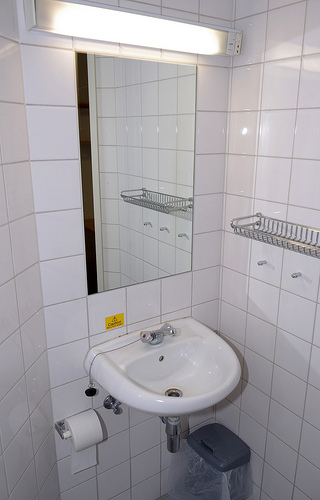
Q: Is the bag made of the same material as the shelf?
A: No, the bag is made of plastic and the shelf is made of metal.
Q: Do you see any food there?
A: No, there is no food.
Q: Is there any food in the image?
A: No, there is no food.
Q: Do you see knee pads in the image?
A: No, there are no knee pads.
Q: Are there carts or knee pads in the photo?
A: No, there are no knee pads or carts.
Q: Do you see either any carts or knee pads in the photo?
A: No, there are no knee pads or carts.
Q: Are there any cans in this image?
A: Yes, there is a can.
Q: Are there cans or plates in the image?
A: Yes, there is a can.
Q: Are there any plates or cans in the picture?
A: Yes, there is a can.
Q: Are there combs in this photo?
A: No, there are no combs.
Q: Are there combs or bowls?
A: No, there are no combs or bowls.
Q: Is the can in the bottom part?
A: Yes, the can is in the bottom of the image.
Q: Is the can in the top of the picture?
A: No, the can is in the bottom of the image.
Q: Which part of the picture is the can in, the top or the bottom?
A: The can is in the bottom of the image.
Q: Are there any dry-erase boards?
A: No, there are no dry-erase boards.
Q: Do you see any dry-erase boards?
A: No, there are no dry-erase boards.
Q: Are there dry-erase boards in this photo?
A: No, there are no dry-erase boards.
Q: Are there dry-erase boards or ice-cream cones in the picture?
A: No, there are no dry-erase boards or ice-cream cones.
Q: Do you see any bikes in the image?
A: No, there are no bikes.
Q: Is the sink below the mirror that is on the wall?
A: Yes, the sink is below the mirror.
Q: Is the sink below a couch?
A: No, the sink is below the mirror.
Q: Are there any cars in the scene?
A: No, there are no cars.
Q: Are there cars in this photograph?
A: No, there are no cars.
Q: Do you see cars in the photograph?
A: No, there are no cars.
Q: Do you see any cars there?
A: No, there are no cars.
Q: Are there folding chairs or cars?
A: No, there are no cars or folding chairs.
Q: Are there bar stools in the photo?
A: No, there are no bar stools.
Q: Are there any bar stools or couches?
A: No, there are no bar stools or couches.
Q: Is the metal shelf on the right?
A: Yes, the shelf is on the right of the image.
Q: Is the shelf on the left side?
A: No, the shelf is on the right of the image.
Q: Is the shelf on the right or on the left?
A: The shelf is on the right of the image.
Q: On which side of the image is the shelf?
A: The shelf is on the right of the image.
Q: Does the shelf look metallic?
A: Yes, the shelf is metallic.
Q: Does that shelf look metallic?
A: Yes, the shelf is metallic.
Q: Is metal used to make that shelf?
A: Yes, the shelf is made of metal.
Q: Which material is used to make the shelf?
A: The shelf is made of metal.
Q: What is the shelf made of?
A: The shelf is made of metal.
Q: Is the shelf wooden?
A: No, the shelf is metallic.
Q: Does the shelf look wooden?
A: No, the shelf is metallic.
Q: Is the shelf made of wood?
A: No, the shelf is made of metal.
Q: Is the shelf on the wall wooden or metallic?
A: The shelf is metallic.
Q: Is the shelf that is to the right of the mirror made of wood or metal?
A: The shelf is made of metal.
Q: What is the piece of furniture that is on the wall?
A: The piece of furniture is a shelf.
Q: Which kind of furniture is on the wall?
A: The piece of furniture is a shelf.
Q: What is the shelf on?
A: The shelf is on the wall.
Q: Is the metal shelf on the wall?
A: Yes, the shelf is on the wall.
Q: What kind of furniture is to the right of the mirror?
A: The piece of furniture is a shelf.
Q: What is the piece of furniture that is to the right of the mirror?
A: The piece of furniture is a shelf.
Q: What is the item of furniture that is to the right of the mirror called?
A: The piece of furniture is a shelf.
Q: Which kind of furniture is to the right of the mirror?
A: The piece of furniture is a shelf.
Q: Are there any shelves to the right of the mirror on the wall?
A: Yes, there is a shelf to the right of the mirror.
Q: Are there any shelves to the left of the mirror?
A: No, the shelf is to the right of the mirror.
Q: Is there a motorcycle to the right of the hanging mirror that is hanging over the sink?
A: No, there is a shelf to the right of the mirror.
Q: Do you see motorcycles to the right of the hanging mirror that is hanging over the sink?
A: No, there is a shelf to the right of the mirror.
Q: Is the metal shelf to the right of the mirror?
A: Yes, the shelf is to the right of the mirror.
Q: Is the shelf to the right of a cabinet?
A: No, the shelf is to the right of the mirror.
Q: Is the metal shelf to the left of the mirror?
A: No, the shelf is to the right of the mirror.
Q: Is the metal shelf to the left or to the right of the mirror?
A: The shelf is to the right of the mirror.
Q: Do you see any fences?
A: No, there are no fences.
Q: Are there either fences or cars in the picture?
A: No, there are no fences or cars.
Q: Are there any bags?
A: Yes, there is a bag.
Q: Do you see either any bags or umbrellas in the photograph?
A: Yes, there is a bag.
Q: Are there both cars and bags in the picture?
A: No, there is a bag but no cars.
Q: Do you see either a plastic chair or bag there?
A: Yes, there is a plastic bag.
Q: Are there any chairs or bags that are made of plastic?
A: Yes, the bag is made of plastic.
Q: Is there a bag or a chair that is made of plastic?
A: Yes, the bag is made of plastic.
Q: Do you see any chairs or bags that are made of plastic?
A: Yes, the bag is made of plastic.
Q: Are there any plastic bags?
A: Yes, there is a bag that is made of plastic.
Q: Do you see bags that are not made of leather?
A: Yes, there is a bag that is made of plastic.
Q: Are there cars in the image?
A: No, there are no cars.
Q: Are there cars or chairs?
A: No, there are no cars or chairs.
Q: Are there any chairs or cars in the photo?
A: No, there are no cars or chairs.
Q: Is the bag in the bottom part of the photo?
A: Yes, the bag is in the bottom of the image.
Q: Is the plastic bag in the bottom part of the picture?
A: Yes, the bag is in the bottom of the image.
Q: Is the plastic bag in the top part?
A: No, the bag is in the bottom of the image.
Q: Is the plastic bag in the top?
A: No, the bag is in the bottom of the image.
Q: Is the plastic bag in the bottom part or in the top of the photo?
A: The bag is in the bottom of the image.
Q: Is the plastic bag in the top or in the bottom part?
A: The bag is in the bottom of the image.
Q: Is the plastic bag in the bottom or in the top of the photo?
A: The bag is in the bottom of the image.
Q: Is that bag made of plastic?
A: Yes, the bag is made of plastic.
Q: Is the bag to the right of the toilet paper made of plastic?
A: Yes, the bag is made of plastic.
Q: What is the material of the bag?
A: The bag is made of plastic.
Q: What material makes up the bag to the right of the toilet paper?
A: The bag is made of plastic.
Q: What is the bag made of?
A: The bag is made of plastic.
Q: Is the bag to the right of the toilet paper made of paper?
A: No, the bag is made of plastic.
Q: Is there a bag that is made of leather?
A: No, there is a bag but it is made of plastic.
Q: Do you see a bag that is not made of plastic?
A: No, there is a bag but it is made of plastic.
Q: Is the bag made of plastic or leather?
A: The bag is made of plastic.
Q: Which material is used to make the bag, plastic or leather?
A: The bag is made of plastic.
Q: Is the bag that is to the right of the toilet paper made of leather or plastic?
A: The bag is made of plastic.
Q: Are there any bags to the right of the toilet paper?
A: Yes, there is a bag to the right of the toilet paper.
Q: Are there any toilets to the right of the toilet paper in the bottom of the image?
A: No, there is a bag to the right of the toilet paper.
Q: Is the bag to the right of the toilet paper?
A: Yes, the bag is to the right of the toilet paper.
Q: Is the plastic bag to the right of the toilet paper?
A: Yes, the bag is to the right of the toilet paper.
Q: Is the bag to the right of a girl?
A: No, the bag is to the right of the toilet paper.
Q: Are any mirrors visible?
A: Yes, there is a mirror.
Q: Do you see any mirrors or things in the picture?
A: Yes, there is a mirror.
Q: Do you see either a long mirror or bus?
A: Yes, there is a long mirror.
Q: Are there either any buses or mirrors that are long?
A: Yes, the mirror is long.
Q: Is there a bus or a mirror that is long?
A: Yes, the mirror is long.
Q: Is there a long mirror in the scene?
A: Yes, there is a long mirror.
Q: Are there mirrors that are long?
A: Yes, there is a mirror that is long.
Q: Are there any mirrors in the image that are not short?
A: Yes, there is a long mirror.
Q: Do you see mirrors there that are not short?
A: Yes, there is a long mirror.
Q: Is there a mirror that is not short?
A: Yes, there is a long mirror.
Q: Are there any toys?
A: No, there are no toys.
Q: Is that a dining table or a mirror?
A: That is a mirror.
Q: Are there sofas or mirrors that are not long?
A: No, there is a mirror but it is long.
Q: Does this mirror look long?
A: Yes, the mirror is long.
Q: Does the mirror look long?
A: Yes, the mirror is long.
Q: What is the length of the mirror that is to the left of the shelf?
A: The mirror is long.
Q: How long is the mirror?
A: The mirror is long.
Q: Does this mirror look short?
A: No, the mirror is long.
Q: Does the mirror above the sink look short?
A: No, the mirror is long.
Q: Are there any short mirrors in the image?
A: No, there is a mirror but it is long.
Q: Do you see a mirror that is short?
A: No, there is a mirror but it is long.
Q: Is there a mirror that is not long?
A: No, there is a mirror but it is long.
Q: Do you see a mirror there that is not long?
A: No, there is a mirror but it is long.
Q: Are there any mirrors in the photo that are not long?
A: No, there is a mirror but it is long.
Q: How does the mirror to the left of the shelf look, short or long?
A: The mirror is long.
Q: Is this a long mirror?
A: Yes, this is a long mirror.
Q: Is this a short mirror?
A: No, this is a long mirror.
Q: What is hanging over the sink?
A: The mirror is hanging over the sink.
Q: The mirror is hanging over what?
A: The mirror is hanging over the sink.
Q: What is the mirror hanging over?
A: The mirror is hanging over the sink.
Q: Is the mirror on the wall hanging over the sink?
A: Yes, the mirror is hanging over the sink.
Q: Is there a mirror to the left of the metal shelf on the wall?
A: Yes, there is a mirror to the left of the shelf.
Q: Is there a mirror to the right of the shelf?
A: No, the mirror is to the left of the shelf.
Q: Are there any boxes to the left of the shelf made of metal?
A: No, there is a mirror to the left of the shelf.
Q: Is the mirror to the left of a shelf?
A: Yes, the mirror is to the left of a shelf.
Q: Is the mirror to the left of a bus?
A: No, the mirror is to the left of a shelf.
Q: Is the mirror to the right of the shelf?
A: No, the mirror is to the left of the shelf.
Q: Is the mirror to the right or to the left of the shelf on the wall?
A: The mirror is to the left of the shelf.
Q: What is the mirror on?
A: The mirror is on the wall.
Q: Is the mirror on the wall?
A: Yes, the mirror is on the wall.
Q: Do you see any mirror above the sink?
A: Yes, there is a mirror above the sink.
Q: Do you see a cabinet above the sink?
A: No, there is a mirror above the sink.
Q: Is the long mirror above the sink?
A: Yes, the mirror is above the sink.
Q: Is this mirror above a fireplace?
A: No, the mirror is above the sink.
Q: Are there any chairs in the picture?
A: No, there are no chairs.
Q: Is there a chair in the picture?
A: No, there are no chairs.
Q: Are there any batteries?
A: No, there are no batteries.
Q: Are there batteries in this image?
A: No, there are no batteries.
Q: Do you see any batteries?
A: No, there are no batteries.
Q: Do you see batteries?
A: No, there are no batteries.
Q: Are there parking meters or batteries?
A: No, there are no batteries or parking meters.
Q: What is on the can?
A: The lid is on the can.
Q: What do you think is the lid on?
A: The lid is on the can.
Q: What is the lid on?
A: The lid is on the can.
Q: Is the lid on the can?
A: Yes, the lid is on the can.